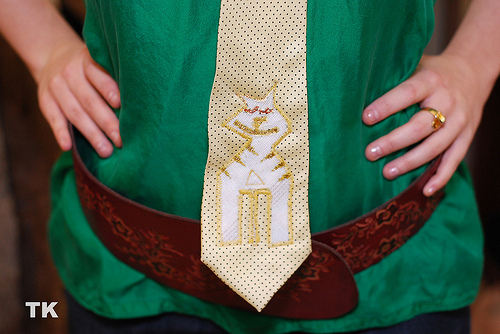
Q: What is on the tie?
A: A cat.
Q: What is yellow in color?
A: The tie.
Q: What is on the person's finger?
A: Ring.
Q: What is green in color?
A: Shirt.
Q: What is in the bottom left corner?
A: Two letters.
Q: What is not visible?
A: Face of person.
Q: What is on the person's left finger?
A: Ring.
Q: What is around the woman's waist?
A: Belt.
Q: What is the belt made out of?
A: Leather.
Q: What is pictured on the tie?
A: Cat.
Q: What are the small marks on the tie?
A: Dots.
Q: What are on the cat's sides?
A: Stripes.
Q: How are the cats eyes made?
A: Stitched.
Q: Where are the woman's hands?
A: Waist.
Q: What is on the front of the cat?
A: Triangle.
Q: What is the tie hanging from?
A: Neck.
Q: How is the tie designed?
A: With an embroidery cat.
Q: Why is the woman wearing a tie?
A: Fun fashion.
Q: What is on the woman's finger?
A: A yellow stone ring.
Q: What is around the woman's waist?
A: A brown leather belt.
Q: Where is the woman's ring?
A: Middle finger on the left hand.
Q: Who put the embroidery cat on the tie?
A: The woman in green.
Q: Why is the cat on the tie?
A: To show embroidery skills.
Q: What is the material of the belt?
A: Leather.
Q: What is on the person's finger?
A: A ring.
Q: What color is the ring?
A: Gold.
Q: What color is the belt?
A: Brown.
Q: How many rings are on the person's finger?
A: One.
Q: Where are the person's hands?
A: On their hips.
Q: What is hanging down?
A: A tie.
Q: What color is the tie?
A: Yellow.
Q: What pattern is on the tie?
A: Dots.